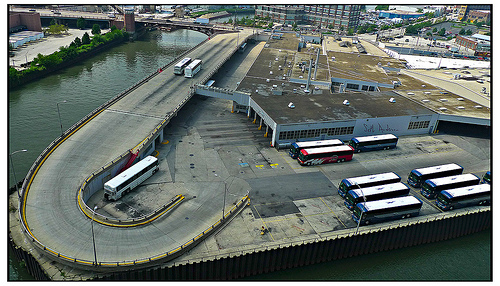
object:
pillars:
[305, 47, 320, 90]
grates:
[232, 148, 272, 173]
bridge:
[7, 5, 242, 34]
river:
[6, 28, 216, 189]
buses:
[480, 170, 493, 183]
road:
[102, 113, 133, 129]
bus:
[406, 162, 465, 187]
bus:
[434, 184, 492, 212]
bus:
[184, 59, 203, 78]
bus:
[347, 131, 398, 152]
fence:
[8, 177, 490, 280]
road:
[28, 43, 57, 53]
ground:
[453, 125, 489, 167]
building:
[245, 89, 492, 150]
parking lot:
[213, 156, 483, 213]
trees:
[6, 20, 127, 86]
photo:
[7, 4, 491, 281]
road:
[130, 90, 168, 115]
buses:
[342, 181, 408, 207]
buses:
[419, 172, 480, 199]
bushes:
[106, 14, 118, 18]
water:
[93, 64, 114, 74]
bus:
[103, 152, 158, 199]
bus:
[172, 58, 192, 76]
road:
[178, 157, 249, 194]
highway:
[6, 5, 494, 267]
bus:
[296, 145, 354, 167]